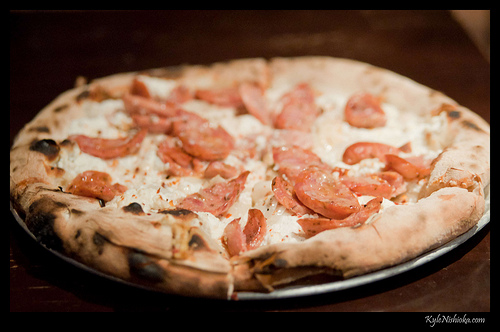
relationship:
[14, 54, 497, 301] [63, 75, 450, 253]
pizza has cheese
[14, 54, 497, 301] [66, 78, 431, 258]
pizza has pepperoni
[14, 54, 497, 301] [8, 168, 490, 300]
pizza on top of dish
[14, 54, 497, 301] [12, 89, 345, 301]
pizza has spots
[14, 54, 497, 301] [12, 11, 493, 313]
pizza on top of table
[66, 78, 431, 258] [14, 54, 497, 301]
pepperoni on top of pizza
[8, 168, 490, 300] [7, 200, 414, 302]
dish has edge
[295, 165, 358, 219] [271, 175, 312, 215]
pepperoni on top of pepperoni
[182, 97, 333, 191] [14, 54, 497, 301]
pepperoni in center of pizza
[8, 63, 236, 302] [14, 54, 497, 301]
crust on left side of pizza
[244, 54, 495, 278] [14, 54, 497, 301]
crust on right side of pizza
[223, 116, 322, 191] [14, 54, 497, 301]
cheese in center of pizza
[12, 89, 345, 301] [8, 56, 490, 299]
spots on crust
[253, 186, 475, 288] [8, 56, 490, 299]
bubble in crust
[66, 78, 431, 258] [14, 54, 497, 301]
pepperoni on pizza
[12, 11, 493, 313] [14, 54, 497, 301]
table under pizza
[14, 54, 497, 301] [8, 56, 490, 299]
pizza has crust